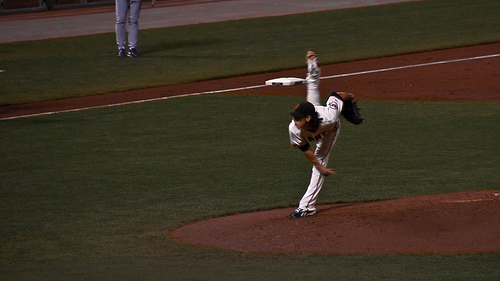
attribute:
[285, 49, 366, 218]
baseball player — pitcher, throwing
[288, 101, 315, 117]
hat — black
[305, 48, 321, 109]
leg — extended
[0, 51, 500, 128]
line — white, white chalk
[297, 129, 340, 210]
trousers — white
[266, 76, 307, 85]
base — white, third base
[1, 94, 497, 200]
grass — green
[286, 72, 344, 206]
uniform — white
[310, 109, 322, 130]
hair — dark